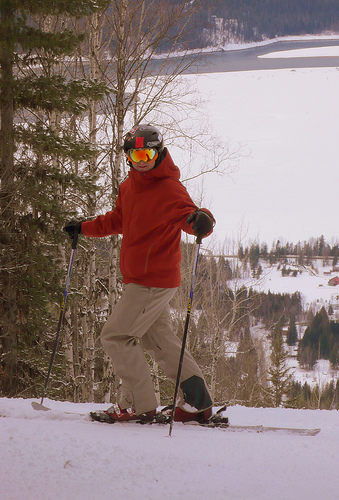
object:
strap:
[111, 398, 121, 416]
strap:
[123, 403, 133, 418]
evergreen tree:
[0, 0, 110, 402]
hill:
[0, 397, 338, 499]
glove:
[183, 206, 215, 244]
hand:
[183, 206, 215, 245]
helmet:
[121, 121, 165, 172]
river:
[9, 35, 338, 125]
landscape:
[0, 0, 338, 499]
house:
[327, 274, 338, 289]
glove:
[61, 217, 82, 245]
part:
[296, 199, 323, 228]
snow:
[14, 66, 339, 388]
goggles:
[127, 144, 158, 165]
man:
[61, 120, 217, 425]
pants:
[95, 277, 214, 415]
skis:
[30, 395, 106, 417]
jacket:
[80, 148, 216, 288]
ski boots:
[105, 391, 158, 426]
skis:
[182, 414, 321, 436]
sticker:
[133, 135, 146, 150]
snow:
[0, 396, 337, 499]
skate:
[32, 120, 321, 441]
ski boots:
[160, 394, 213, 426]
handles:
[69, 228, 79, 250]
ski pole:
[31, 234, 79, 412]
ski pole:
[165, 225, 203, 437]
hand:
[60, 214, 81, 254]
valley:
[158, 256, 338, 412]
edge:
[168, 391, 178, 439]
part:
[42, 297, 74, 404]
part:
[130, 400, 168, 427]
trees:
[259, 313, 295, 406]